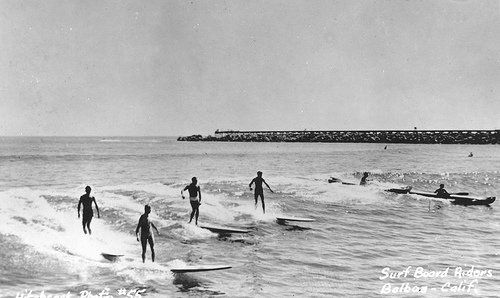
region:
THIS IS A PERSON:
[70, 178, 99, 245]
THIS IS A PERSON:
[130, 190, 174, 265]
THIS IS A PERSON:
[185, 171, 207, 243]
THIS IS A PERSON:
[248, 139, 283, 224]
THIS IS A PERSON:
[353, 168, 385, 195]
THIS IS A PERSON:
[425, 176, 462, 203]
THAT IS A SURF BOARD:
[112, 245, 228, 282]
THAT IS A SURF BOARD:
[184, 225, 260, 244]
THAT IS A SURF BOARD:
[263, 208, 320, 239]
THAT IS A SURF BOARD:
[371, 171, 419, 201]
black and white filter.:
[2, 2, 494, 288]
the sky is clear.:
[3, 0, 491, 127]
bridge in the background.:
[194, 118, 499, 153]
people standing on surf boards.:
[67, 160, 299, 285]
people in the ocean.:
[65, 165, 307, 275]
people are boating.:
[327, 164, 499, 218]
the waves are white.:
[5, 178, 278, 267]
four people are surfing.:
[67, 165, 301, 282]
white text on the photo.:
[370, 255, 494, 292]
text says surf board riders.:
[366, 251, 494, 285]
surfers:
[65, 187, 171, 250]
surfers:
[162, 141, 274, 231]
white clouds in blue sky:
[32, 30, 66, 65]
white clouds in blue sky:
[255, 50, 285, 62]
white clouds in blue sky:
[177, 49, 219, 96]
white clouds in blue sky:
[373, 10, 409, 51]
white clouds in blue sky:
[109, 48, 159, 94]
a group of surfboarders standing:
[73, 169, 313, 274]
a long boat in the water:
[328, 173, 493, 206]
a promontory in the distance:
[287, 124, 498, 148]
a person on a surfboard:
[132, 203, 159, 263]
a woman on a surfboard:
[75, 185, 97, 238]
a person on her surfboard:
[77, 187, 99, 236]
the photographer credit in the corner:
[373, 266, 498, 293]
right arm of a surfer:
[180, 185, 190, 200]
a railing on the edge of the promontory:
[212, 129, 499, 134]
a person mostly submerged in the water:
[465, 150, 478, 158]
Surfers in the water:
[51, 170, 308, 279]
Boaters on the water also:
[326, 168, 498, 207]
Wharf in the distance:
[213, 124, 498, 142]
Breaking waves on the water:
[1, 188, 237, 285]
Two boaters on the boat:
[360, 168, 450, 196]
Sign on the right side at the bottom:
[378, 265, 497, 297]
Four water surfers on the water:
[77, 165, 295, 259]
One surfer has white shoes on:
[185, 192, 205, 206]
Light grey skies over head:
[3, 2, 497, 131]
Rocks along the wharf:
[179, 135, 497, 145]